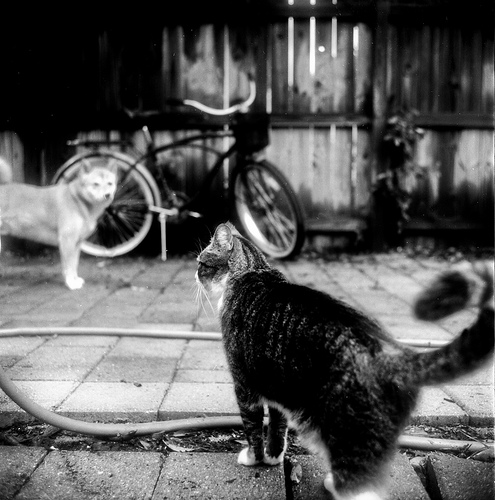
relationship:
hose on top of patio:
[0, 327, 494, 461] [2, 232, 491, 498]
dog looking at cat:
[1, 158, 118, 289] [194, 222, 494, 498]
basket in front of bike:
[232, 110, 272, 155] [51, 72, 304, 260]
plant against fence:
[353, 93, 426, 256] [2, 2, 494, 250]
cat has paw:
[194, 222, 494, 498] [237, 445, 262, 466]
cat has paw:
[194, 222, 494, 498] [263, 445, 284, 466]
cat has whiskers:
[194, 222, 494, 498] [196, 288, 217, 324]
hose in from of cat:
[0, 327, 494, 461] [194, 222, 494, 498]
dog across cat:
[1, 158, 118, 289] [194, 222, 494, 498]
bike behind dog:
[51, 72, 304, 260] [1, 158, 118, 289]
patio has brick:
[2, 232, 491, 498] [55, 377, 170, 420]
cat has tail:
[194, 222, 494, 498] [392, 261, 494, 387]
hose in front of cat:
[0, 327, 494, 461] [194, 222, 494, 498]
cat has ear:
[194, 222, 494, 498] [208, 223, 235, 255]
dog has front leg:
[1, 158, 118, 289] [56, 214, 84, 288]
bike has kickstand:
[51, 72, 304, 260] [157, 211, 168, 264]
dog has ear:
[1, 158, 118, 289] [79, 156, 89, 176]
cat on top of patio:
[194, 222, 494, 498] [2, 232, 491, 498]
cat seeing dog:
[194, 222, 494, 498] [1, 158, 118, 289]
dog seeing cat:
[1, 158, 118, 289] [194, 222, 494, 498]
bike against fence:
[51, 72, 304, 260] [2, 2, 494, 250]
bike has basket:
[51, 72, 304, 260] [232, 110, 272, 155]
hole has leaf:
[1, 417, 494, 451] [160, 436, 194, 452]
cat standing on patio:
[194, 222, 494, 498] [2, 232, 491, 498]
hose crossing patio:
[0, 327, 494, 461] [2, 232, 491, 498]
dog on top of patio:
[1, 158, 118, 289] [2, 232, 491, 498]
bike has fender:
[51, 72, 304, 260] [227, 153, 264, 205]